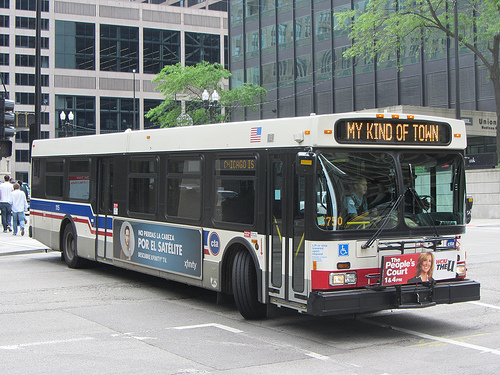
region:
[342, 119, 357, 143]
The letter is orange.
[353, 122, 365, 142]
The letter is orange.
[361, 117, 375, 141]
The letter is orange.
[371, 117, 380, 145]
The letter is orange.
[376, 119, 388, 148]
The letter is orange.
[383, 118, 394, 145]
The letter is orange.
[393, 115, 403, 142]
The letter is orange.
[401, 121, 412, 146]
The letter is orange.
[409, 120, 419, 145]
The letter is orange.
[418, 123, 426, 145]
The letter is orange.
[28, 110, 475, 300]
a bus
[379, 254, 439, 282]
a banner on the bus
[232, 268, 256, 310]
a tire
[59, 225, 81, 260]
the back tire of the bus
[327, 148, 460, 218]
a windshield on the bus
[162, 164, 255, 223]
the windows on the bus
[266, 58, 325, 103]
electrical lines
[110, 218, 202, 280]
banner on the bus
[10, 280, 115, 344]
the ground is grey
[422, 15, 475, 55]
treee branches on the tree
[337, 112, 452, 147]
yellow text on a bus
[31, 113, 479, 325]
long white bus parked on street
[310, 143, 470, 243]
windshield of a bus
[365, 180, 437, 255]
windshield wipers on a bus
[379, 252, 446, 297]
red sign on a bus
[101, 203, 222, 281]
blue sign on the side of a bus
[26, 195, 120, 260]
blue stripe on bus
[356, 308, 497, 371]
white line painted on ground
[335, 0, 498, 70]
green leaves on a tree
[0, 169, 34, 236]
people walking on street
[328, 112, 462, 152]
lit up black and orange sign on bus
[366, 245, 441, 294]
advertisement billboard on front of bus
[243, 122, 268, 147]
American flag sticker on top of bus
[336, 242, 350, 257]
blue and white handicapped sign on bus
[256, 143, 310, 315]
closed doors with windows on bus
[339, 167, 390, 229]
bus driver seen through windshield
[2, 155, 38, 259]
people walking away from the large bus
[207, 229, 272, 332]
tire of the bus turned outwards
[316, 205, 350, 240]
bus number lit up in the windshield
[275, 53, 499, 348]
front of bus in front of large glass building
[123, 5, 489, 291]
a bus on the raod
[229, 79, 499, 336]
a bus on the street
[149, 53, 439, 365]
a passenger bus on teh road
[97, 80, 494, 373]
a passenger bus on the road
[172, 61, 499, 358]
a large bus on teh road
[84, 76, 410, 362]
a large bus on the road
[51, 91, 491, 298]
a large passenger bus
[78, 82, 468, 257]
a large passenger bus on the road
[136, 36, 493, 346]
a large passenger bus onthe street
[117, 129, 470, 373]
a bus that is turning